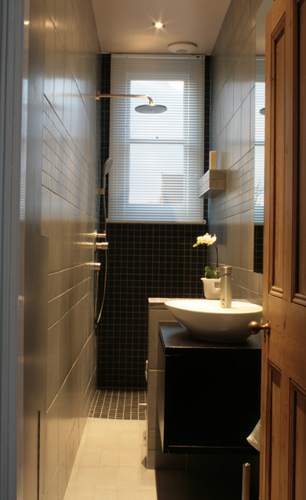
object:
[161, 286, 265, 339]
sink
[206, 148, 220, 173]
candle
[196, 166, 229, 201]
shelf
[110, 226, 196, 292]
wall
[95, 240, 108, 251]
knob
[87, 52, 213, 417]
shower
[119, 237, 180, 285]
tile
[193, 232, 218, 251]
bloom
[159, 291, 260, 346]
sink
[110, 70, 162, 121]
spiquet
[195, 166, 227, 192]
shelf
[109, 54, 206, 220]
blinds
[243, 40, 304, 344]
cabinet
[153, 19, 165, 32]
light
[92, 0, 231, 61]
ceiling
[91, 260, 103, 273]
knob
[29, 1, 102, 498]
wall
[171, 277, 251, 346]
bowl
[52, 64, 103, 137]
wall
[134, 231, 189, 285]
wall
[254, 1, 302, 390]
door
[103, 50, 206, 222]
shades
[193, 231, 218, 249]
flower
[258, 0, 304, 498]
door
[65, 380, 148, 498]
floor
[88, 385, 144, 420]
part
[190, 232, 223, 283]
plant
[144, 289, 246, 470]
table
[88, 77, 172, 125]
shower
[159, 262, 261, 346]
sink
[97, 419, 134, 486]
tile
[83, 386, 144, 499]
floor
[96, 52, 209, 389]
tile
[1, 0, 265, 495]
wall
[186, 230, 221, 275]
orchid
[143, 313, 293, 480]
bathroom vanity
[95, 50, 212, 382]
wall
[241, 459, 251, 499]
handle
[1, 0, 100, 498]
tiled wall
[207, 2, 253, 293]
tiled wall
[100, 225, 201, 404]
tiled wall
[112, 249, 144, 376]
tile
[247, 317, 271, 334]
brass knob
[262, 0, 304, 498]
door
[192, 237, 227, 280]
leaf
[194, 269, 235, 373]
spiket